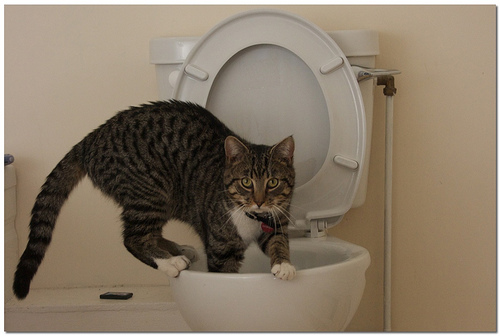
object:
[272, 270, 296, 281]
paw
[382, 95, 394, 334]
pipe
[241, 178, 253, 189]
eye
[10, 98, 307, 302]
cat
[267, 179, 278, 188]
eye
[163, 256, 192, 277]
paw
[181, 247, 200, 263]
paw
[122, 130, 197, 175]
stripes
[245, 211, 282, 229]
collar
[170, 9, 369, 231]
toilet seat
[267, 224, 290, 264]
leg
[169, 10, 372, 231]
seat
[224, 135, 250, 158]
ear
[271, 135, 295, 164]
ear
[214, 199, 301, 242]
whiskers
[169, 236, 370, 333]
toilet bowl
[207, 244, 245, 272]
leg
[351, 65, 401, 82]
handle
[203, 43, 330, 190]
tank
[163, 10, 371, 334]
toilet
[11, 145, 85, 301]
tail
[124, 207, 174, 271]
leg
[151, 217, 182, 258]
leg